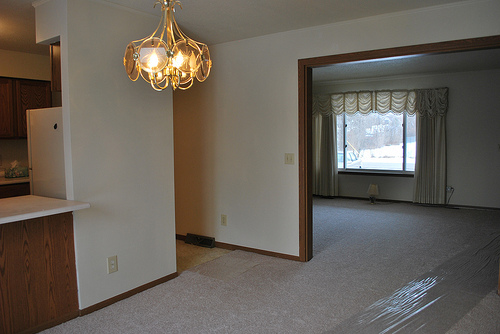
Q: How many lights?
A: One.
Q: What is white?
A: Walls.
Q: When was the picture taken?
A: Daytime.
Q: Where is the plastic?
A: On the carpet.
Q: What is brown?
A: Trim.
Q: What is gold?
A: Light.